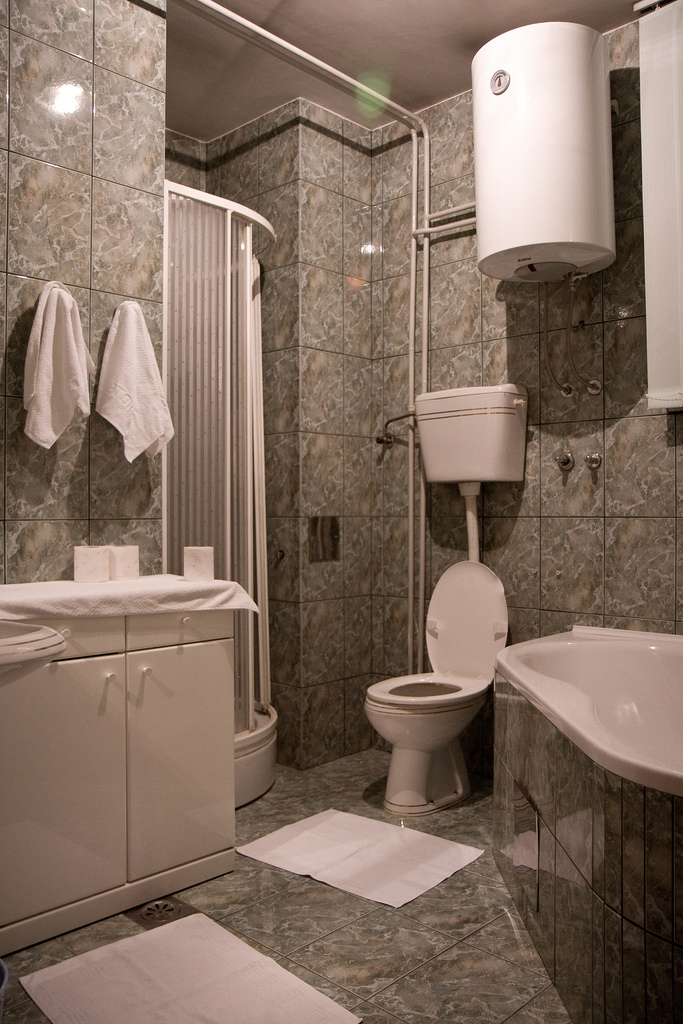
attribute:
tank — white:
[419, 17, 654, 302]